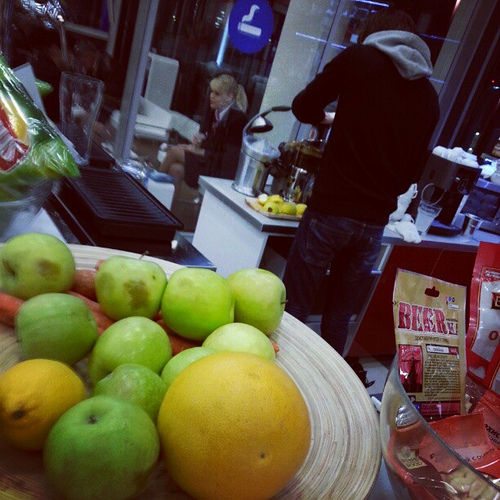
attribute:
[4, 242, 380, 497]
plate — big 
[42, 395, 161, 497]
apple — green 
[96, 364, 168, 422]
apple — green 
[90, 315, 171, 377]
apple — green 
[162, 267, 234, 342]
apple — green 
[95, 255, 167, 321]
apple — green 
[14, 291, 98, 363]
apple — green 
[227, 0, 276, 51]
sign — blue 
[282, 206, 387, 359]
jeans — blue 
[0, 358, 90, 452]
lemon — yellow 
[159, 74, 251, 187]
woman — blonde  , sitting 